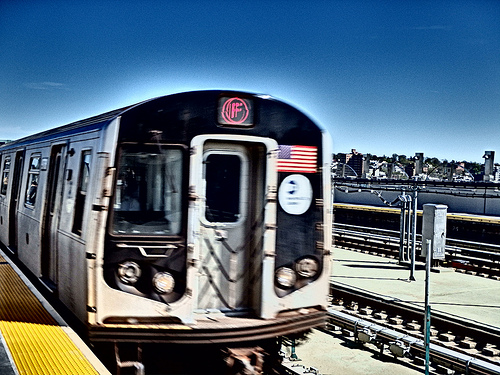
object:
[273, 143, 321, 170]
flag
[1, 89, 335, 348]
train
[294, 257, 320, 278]
headlight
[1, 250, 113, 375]
platform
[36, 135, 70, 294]
door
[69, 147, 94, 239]
window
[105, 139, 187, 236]
front window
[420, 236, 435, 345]
sign post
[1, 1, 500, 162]
sky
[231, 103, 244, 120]
letter f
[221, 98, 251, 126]
circle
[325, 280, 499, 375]
tracks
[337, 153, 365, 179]
buildings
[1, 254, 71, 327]
shadow